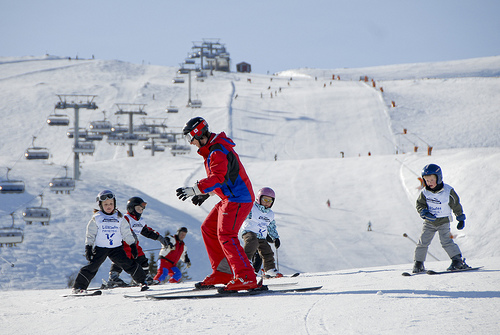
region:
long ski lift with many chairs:
[0, 38, 230, 250]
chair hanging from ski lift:
[25, 130, 47, 160]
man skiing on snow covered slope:
[172, 115, 267, 295]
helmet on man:
[180, 115, 207, 141]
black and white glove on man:
[170, 180, 190, 200]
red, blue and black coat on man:
[196, 130, 258, 200]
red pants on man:
[200, 197, 250, 277]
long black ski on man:
[145, 280, 321, 300]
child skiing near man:
[56, 187, 152, 292]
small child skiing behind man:
[241, 185, 298, 277]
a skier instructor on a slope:
[125, 122, 320, 298]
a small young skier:
[66, 184, 151, 299]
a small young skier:
[403, 162, 483, 274]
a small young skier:
[240, 184, 291, 279]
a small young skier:
[99, 192, 170, 288]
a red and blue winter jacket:
[193, 127, 257, 204]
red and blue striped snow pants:
[193, 196, 254, 276]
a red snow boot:
[224, 269, 258, 287]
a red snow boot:
[197, 267, 232, 287]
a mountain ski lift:
[1, 38, 231, 253]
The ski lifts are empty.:
[0, 2, 235, 270]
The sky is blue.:
[1, 0, 499, 86]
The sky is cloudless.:
[2, 0, 498, 81]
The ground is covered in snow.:
[2, 50, 499, 334]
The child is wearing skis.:
[378, 158, 490, 287]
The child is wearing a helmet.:
[375, 144, 487, 297]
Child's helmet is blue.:
[390, 142, 495, 283]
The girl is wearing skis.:
[58, 177, 165, 303]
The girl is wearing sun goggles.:
[56, 176, 163, 304]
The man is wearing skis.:
[144, 97, 335, 310]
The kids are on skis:
[36, 103, 476, 305]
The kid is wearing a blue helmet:
[401, 146, 476, 211]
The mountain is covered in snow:
[15, 51, 490, 315]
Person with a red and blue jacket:
[148, 107, 318, 312]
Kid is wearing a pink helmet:
[236, 176, 304, 253]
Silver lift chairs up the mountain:
[0, 46, 249, 232]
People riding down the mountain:
[229, 72, 371, 175]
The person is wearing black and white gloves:
[161, 170, 224, 227]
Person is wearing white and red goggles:
[168, 115, 224, 151]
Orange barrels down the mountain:
[332, 69, 451, 172]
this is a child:
[390, 162, 477, 278]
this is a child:
[63, 182, 141, 293]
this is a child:
[121, 190, 161, 281]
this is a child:
[235, 185, 315, 283]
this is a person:
[172, 98, 260, 295]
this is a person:
[155, 217, 200, 284]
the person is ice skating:
[179, 115, 269, 320]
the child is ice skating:
[407, 124, 479, 286]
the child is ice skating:
[243, 179, 298, 281]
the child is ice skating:
[71, 186, 145, 306]